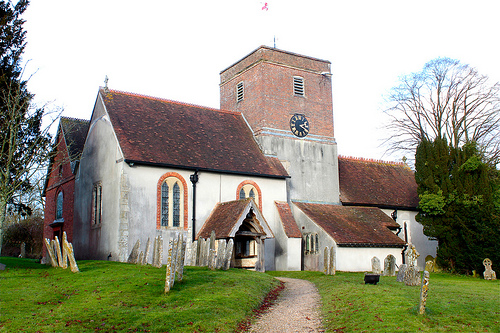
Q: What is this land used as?
A: A graveyard.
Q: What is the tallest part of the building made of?
A: Bricks.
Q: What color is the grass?
A: Green.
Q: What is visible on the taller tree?
A: Branches.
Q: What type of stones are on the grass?
A: Headstones.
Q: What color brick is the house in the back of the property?
A: Red.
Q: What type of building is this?
A: A church.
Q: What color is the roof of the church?
A: Red.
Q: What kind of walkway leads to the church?
A: A tar foot path.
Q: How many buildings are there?
A: One.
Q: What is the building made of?
A: Cement.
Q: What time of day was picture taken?
A: Daytime.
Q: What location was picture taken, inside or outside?
A: Outside.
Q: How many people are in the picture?
A: None.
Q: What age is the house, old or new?
A: Old.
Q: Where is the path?
A: It leads up to the house.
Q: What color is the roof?
A: Brown.